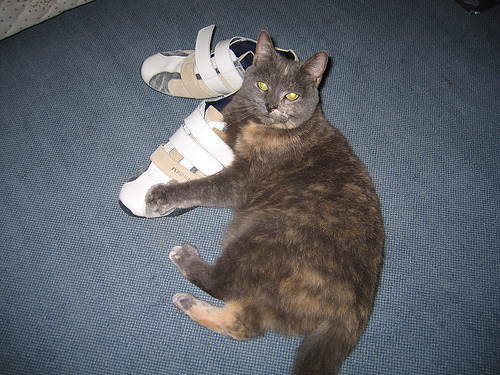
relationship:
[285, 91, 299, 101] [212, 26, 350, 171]
eye of cat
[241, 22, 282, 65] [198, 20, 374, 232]
ear of cat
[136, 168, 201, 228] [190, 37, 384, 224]
paw of cat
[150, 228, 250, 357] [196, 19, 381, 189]
legs of cat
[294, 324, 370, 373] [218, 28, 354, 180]
tail of cat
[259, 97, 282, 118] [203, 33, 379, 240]
nose of cat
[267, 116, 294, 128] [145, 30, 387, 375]
mouth of cat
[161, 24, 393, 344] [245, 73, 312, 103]
cat with eyes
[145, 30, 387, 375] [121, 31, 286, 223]
cat playing with sandals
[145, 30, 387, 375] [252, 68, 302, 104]
cat has eyes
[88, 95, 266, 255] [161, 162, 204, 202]
sandals has brand name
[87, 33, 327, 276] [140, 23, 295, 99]
sandals have sandals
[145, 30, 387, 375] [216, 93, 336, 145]
cat has whiskers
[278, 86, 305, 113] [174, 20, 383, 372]
eye of a cat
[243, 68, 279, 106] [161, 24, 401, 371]
eye of a cat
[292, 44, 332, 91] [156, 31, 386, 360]
ear of a cat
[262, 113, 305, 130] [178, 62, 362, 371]
mouth of cat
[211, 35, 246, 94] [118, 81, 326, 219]
strap on sandals